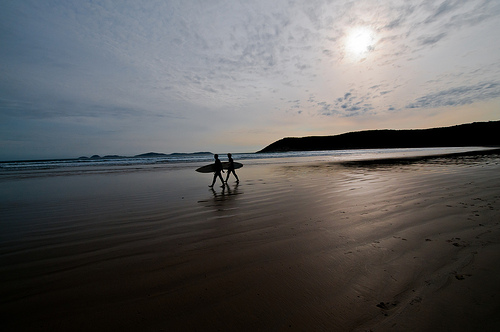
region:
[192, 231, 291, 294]
Wet sand on the beach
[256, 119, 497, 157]
Distant mountains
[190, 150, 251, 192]
Silhouette of two people with a surfboard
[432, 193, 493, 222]
Footprints in wet sand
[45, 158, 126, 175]
Waves at the beach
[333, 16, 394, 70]
Sun behind clouds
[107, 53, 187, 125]
Slightly cloudy sky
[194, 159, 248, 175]
Silhouette of a surfboard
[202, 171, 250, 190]
Four legs of two people walking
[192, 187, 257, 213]
Shadow of two people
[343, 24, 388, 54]
the sun in the sky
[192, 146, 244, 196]
two people walking with surfboards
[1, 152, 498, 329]
the beach and the ocean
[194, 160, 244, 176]
the surf boards that the two people are carrying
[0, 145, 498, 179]
The ocean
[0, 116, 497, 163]
bits of land by or in the ocean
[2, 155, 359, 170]
a small ocean wave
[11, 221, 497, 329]
the sand on the beach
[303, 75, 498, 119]
small dark clouds in the sky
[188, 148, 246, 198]
two surfers walking to the water line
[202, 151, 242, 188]
Two people on the beach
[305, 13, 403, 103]
Sun Setting in the night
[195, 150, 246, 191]
Two people carrying surf board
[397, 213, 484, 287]
Footprints in the sand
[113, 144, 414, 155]
Waves hitting the beach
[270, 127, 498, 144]
Mountain in the backdrop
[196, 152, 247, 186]
Two people carrying surfboard on beach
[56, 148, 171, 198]
Wet sand on the beach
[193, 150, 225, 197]
Man walking on the beach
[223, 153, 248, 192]
Woman walking on beach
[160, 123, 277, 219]
two surfers on the beach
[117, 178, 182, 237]
beach beneath the people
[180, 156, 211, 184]
edge of the board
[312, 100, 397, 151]
hills next to the people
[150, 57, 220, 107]
cloud above the people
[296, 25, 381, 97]
sun behind the clouds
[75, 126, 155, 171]
hills in the background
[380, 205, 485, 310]
footprints in the sand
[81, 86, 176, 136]
sky above the land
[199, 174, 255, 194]
legs of the people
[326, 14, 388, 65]
a sun shining in a cloudy sky.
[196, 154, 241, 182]
a surfboard being carried by two people.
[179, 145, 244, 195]
people carrying a surfboard.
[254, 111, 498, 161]
A mountain range near a beach.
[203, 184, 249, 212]
a shadow on a beach.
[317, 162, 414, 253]
the sun reflecting on the sun.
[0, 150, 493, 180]
an ocearn near a beach.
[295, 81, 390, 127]
a cloud in a sky.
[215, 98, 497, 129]
a section of orange sky.